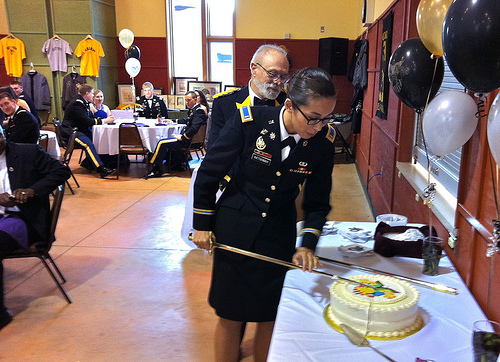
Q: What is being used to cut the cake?
A: Sword.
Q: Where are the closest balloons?
A: On the wall.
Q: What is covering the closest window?
A: Blinds.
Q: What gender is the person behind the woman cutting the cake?
A: Male.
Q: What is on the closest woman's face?
A: Glasses.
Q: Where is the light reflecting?
A: Floor.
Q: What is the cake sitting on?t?
A: Table.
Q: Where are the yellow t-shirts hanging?
A: On the wall.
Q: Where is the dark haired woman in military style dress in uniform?
A: Front of military man.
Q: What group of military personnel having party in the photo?
A: The ones that are sitting standing.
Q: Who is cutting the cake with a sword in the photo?
A: Woman wearing glasses.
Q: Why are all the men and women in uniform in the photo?
A: In the military.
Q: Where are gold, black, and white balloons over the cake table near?
A: Window with blinds.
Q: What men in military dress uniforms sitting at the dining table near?
A: Four men near two white balloons.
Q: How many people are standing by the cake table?
A: Two.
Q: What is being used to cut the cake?
A: A sword.